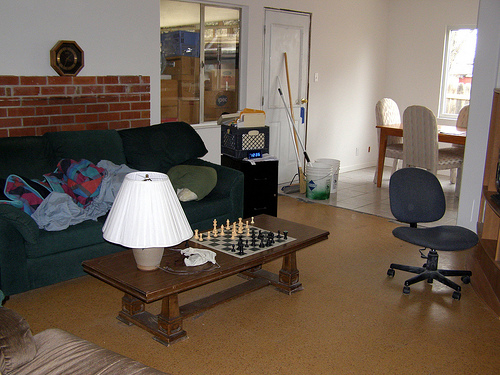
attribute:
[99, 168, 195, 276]
lamp — tan, small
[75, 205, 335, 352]
table — wood, brown, wooden, large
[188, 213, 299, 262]
game — chess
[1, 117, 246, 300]
sofa — comfy, green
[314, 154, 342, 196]
buckets — large, white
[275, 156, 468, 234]
floor — dining room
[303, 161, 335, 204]
buckets — large, white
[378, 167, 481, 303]
chair — grey, blue, rolling, dark grey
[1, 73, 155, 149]
wall — brick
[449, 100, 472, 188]
chair — white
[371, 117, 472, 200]
table — wood, brown, dining room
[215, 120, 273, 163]
crate — milk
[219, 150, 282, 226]
cabinet — filing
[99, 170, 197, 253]
shade — large, white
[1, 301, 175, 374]
couch — brown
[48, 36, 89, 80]
clock — octagon, gold, black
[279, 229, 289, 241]
pieces — black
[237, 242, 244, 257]
pieces — black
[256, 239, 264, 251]
pieces — black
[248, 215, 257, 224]
pieces — white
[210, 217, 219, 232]
pieces — white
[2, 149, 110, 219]
quilt — red, blue, black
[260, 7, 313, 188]
door — white